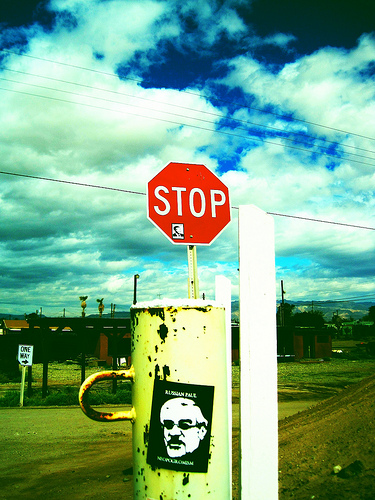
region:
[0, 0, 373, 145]
puffy clouds in the sky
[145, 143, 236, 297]
"stop" sign attached to metal pole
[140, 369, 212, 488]
black and white poster of a man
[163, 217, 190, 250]
black and white sticker of a man stuck on sign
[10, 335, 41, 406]
One way sign on side of road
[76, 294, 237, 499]
large metal post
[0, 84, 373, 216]
wires in the air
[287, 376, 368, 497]
dirt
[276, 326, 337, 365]
brick building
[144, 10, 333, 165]
blue sky peeking through clouds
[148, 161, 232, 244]
A red stop sign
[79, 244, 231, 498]
Sign pole sticking in a rusted column with handle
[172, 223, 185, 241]
Persons photo on stop sign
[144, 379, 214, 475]
Flyer of a person on rusted column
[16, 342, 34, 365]
A One Way sign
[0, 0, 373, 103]
A blue cloudy sky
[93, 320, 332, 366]
A building in the background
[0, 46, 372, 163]
Electrical wires in the air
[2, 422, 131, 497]
A grassy area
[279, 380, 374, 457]
An up hill grassy area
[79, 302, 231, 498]
large yellow and black rusty metal pole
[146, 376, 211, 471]
black and white sticker with face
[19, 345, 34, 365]
one way black and white sign with arrow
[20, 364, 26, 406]
long yellow metal pole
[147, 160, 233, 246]
red and white stop sign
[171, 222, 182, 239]
black and white sticker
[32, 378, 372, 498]
pile of brown dirt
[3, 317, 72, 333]
brown slanted roof of house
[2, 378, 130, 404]
patch of green grass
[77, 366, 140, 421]
yellow rusty U hook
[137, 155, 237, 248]
Stop sign on pole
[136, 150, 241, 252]
Stop sign is red with white border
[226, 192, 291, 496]
White pole next to sign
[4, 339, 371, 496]
Field covered with grass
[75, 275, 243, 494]
Cylindrical cement structure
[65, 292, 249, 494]
Cylindrical structure has a rusty handle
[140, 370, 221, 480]
Posted showing a face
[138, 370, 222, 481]
Poster background is black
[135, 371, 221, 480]
Poster depict a man wearing glasses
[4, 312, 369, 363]
Buildings on background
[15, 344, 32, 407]
The one way sign on the left.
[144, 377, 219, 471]
The black and white sticker on the cement post.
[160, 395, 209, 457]
The face of the man on the sticker.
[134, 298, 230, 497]
The cement post the sticker is glued to.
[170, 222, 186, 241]
The black and white sticker on the stop sign.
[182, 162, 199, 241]
The two screws on the stop sign.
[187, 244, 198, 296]
The metal pole the stop sign is mounted on.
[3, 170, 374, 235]
The wire behind the stop sign.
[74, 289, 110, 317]
The two palm trees in the background.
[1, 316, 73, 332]
The house with the brown roof in the background.